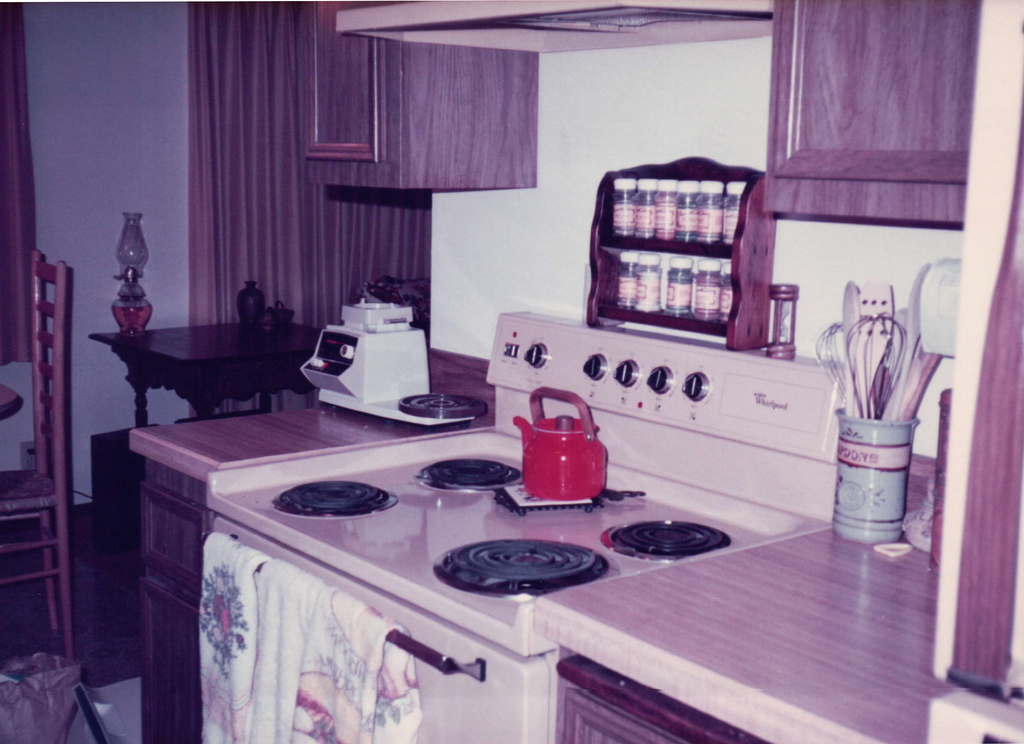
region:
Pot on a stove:
[510, 368, 618, 509]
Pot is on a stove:
[509, 370, 623, 500]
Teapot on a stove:
[498, 362, 609, 502]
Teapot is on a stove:
[497, 364, 622, 508]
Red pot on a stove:
[473, 359, 619, 505]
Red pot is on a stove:
[513, 370, 628, 526]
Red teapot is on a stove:
[495, 365, 619, 496]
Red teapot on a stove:
[509, 368, 624, 509]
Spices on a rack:
[579, 165, 769, 342]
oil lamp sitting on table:
[106, 206, 158, 342]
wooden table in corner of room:
[81, 315, 334, 427]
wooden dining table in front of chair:
[5, 256, 85, 664]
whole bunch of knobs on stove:
[521, 334, 717, 405]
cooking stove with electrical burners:
[198, 304, 846, 741]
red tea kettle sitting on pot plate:
[503, 383, 614, 505]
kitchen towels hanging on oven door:
[193, 531, 427, 741]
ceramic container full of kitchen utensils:
[821, 256, 959, 547]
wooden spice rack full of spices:
[582, 154, 773, 352]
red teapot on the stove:
[517, 392, 606, 501]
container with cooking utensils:
[825, 260, 950, 540]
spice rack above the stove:
[583, 148, 774, 346]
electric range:
[245, 418, 796, 654]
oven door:
[203, 516, 523, 741]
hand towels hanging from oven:
[198, 554, 415, 736]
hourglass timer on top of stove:
[763, 285, 795, 362]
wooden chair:
[4, 253, 74, 664]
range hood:
[337, 10, 771, 59]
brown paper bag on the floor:
[0, 651, 84, 735]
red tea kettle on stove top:
[492, 385, 619, 532]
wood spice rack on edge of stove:
[570, 148, 789, 363]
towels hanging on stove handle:
[173, 508, 465, 734]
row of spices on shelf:
[593, 170, 758, 253]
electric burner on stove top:
[437, 526, 605, 606]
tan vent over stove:
[321, 4, 771, 564]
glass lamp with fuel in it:
[109, 208, 154, 338]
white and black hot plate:
[298, 299, 482, 429]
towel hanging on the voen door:
[310, 568, 434, 739]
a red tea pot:
[512, 353, 595, 505]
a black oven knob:
[677, 363, 707, 433]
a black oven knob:
[647, 359, 652, 389]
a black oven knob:
[581, 356, 600, 394]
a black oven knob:
[538, 321, 551, 369]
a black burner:
[439, 524, 596, 605]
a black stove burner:
[632, 497, 715, 540]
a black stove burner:
[298, 448, 372, 522]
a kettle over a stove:
[501, 374, 623, 522]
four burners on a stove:
[263, 450, 756, 615]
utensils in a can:
[807, 288, 937, 561]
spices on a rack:
[569, 136, 783, 358]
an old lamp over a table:
[86, 192, 167, 361]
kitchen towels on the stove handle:
[173, 512, 469, 740]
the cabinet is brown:
[288, 9, 549, 206]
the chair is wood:
[6, 243, 87, 658]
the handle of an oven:
[380, 610, 520, 686]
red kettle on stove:
[445, 325, 701, 557]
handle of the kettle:
[512, 367, 618, 450]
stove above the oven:
[264, 407, 701, 643]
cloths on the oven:
[142, 537, 433, 741]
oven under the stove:
[179, 538, 525, 732]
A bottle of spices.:
[717, 261, 737, 318]